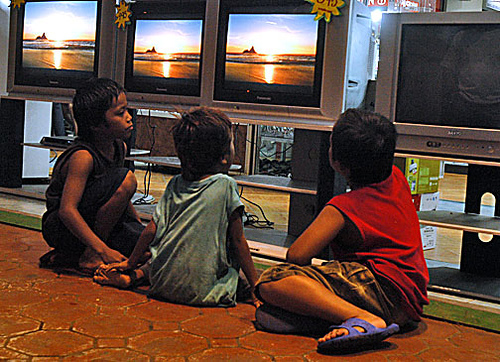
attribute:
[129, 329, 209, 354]
brick — red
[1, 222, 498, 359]
floor — circular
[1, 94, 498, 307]
shelves — open backed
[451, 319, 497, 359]
stone — red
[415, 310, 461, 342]
stone — red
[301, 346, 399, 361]
brick — red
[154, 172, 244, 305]
shirt — green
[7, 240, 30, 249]
brick — red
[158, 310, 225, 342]
brick — red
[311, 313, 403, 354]
sandal — purple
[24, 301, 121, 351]
stone — red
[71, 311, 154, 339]
brick — red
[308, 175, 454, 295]
shirt — red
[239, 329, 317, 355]
brick — red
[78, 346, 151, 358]
brick — red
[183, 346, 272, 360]
brick — red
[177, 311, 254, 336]
brick — red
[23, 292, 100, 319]
brick — red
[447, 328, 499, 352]
brick — red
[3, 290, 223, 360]
brick — red 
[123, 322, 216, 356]
brick — red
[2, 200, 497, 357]
stone — red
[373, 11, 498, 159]
television — Off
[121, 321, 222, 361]
stone — red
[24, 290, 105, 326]
brick — red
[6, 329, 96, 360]
tiles — red